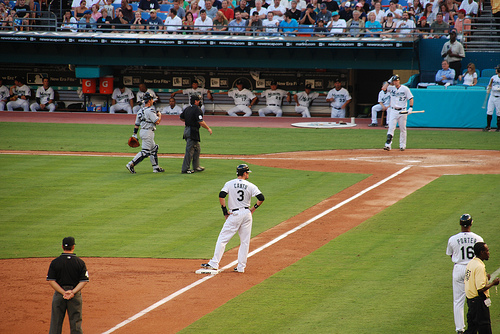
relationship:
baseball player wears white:
[123, 90, 165, 167] [206, 175, 262, 273]